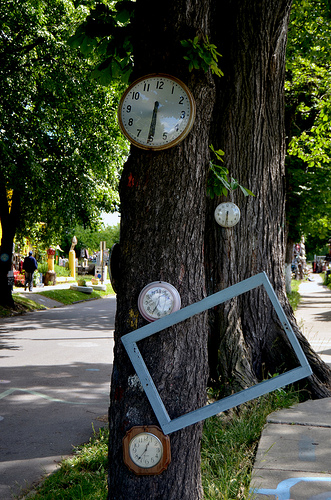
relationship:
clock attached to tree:
[114, 69, 198, 153] [110, 0, 221, 499]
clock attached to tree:
[135, 275, 184, 327] [110, 0, 221, 499]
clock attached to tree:
[119, 421, 174, 479] [110, 0, 221, 499]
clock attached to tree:
[212, 199, 244, 229] [199, 1, 330, 413]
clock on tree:
[119, 421, 174, 479] [110, 0, 221, 499]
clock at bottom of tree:
[119, 421, 174, 479] [110, 0, 221, 499]